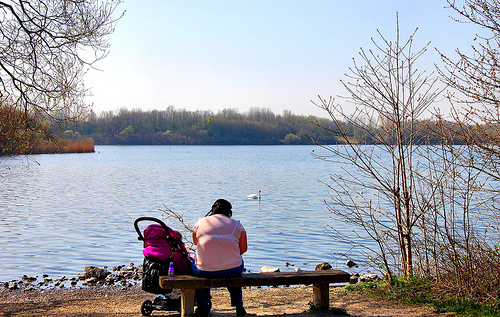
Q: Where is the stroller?
A: Next to the woman.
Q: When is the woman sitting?
A: Daytime.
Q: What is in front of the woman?
A: Water.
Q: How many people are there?
A: One.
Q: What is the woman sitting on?
A: Bench.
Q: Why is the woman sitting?
A: Resting.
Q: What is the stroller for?
A: Baby.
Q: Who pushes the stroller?
A: The woman.